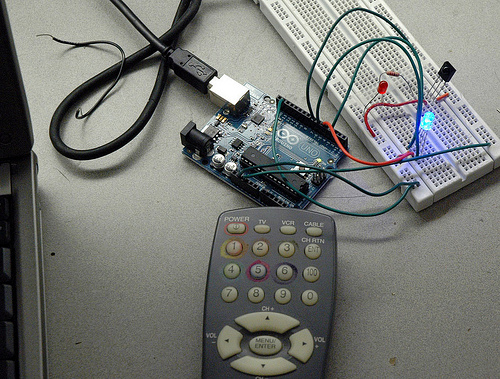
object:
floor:
[57, 235, 177, 376]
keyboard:
[216, 223, 321, 376]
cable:
[364, 100, 418, 138]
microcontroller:
[179, 74, 348, 211]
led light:
[419, 112, 435, 131]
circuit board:
[254, 0, 500, 213]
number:
[233, 242, 235, 249]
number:
[282, 267, 288, 275]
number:
[253, 288, 259, 297]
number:
[307, 292, 313, 300]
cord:
[35, 34, 125, 119]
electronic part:
[213, 101, 345, 205]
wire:
[236, 6, 489, 214]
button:
[307, 227, 322, 237]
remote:
[200, 205, 338, 379]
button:
[280, 225, 296, 234]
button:
[254, 224, 270, 233]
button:
[305, 244, 321, 259]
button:
[278, 241, 295, 257]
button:
[253, 241, 269, 256]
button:
[226, 241, 242, 256]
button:
[277, 265, 293, 281]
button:
[250, 264, 266, 279]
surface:
[155, 232, 207, 379]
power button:
[227, 222, 246, 233]